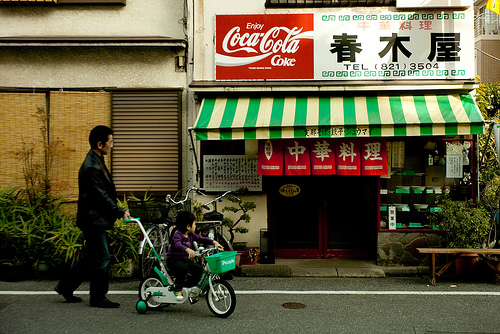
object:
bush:
[424, 199, 492, 249]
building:
[0, 0, 192, 220]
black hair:
[86, 124, 117, 153]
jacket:
[74, 149, 126, 230]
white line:
[0, 290, 499, 295]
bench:
[415, 248, 499, 287]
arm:
[173, 235, 189, 252]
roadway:
[0, 275, 499, 333]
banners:
[256, 140, 283, 176]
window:
[111, 93, 179, 190]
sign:
[215, 13, 312, 79]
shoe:
[53, 286, 82, 303]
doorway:
[267, 173, 377, 260]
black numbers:
[380, 62, 388, 71]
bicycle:
[122, 218, 240, 320]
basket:
[203, 250, 237, 274]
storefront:
[182, 0, 489, 260]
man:
[53, 124, 136, 309]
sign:
[359, 137, 388, 176]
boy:
[164, 210, 226, 293]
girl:
[165, 210, 227, 291]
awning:
[189, 92, 484, 141]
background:
[0, 0, 499, 333]